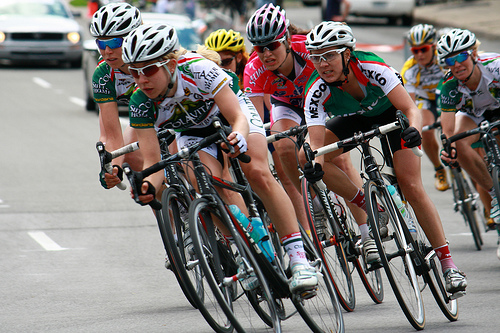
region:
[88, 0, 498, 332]
bike riders on street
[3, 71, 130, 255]
dotted line on the street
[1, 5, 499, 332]
the grey pavement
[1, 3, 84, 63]
a silver vehicle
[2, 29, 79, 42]
lights on on car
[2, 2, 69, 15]
windshield of car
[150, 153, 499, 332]
the bike tires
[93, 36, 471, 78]
goggles on riders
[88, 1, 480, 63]
all helmets on riders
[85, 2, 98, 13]
a red hydrant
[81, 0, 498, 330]
Seven bicycle race contestants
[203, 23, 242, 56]
Yellow helmet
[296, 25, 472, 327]
A bike racer from Mexico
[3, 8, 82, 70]
A car in the backgound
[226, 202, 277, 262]
Two blue water bottles on the bicycle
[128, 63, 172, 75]
A bike racer wearing sunglasses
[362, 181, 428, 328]
Wheel of a bike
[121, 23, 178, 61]
White bike helmet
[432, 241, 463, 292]
White shoes and red sock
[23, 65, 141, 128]
White lane markings on the asphalt road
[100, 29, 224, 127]
the head of a woman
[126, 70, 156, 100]
the nose of a woman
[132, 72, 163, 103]
the mouth of a woman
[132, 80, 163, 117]
the lips of a woman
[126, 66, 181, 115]
the chin of a woman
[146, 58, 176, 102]
the cheek of a woman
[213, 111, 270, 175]
the hand of a woman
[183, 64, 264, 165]
the arm of a woman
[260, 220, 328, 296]
the foot of a woman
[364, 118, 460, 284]
the leg of a woman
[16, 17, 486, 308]
people in a cycling race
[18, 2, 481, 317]
women cycling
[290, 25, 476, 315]
woman representing Mexico in the race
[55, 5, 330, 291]
two women representing Italy.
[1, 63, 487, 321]
women cycling on asphalt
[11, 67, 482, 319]
women cycling in the street with traffic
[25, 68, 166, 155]
white lines that indicate the division of lanes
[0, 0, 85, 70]
car in the street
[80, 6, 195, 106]
car switching lanes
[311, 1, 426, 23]
back of car on the side of the road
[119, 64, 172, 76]
Sunglasses on bike rider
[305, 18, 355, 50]
Helmet on bike rider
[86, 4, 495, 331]
Bicycle races leaning into right turn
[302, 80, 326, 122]
Mexico written on jersey sleeve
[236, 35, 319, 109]
Red jersey on bike racer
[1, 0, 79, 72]
Car following race with lights on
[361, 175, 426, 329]
Front wheel of racing bike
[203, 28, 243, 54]
Yellow helmet on racer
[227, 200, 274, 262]
Water bottle on bike frame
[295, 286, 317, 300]
Pedal on racing bike